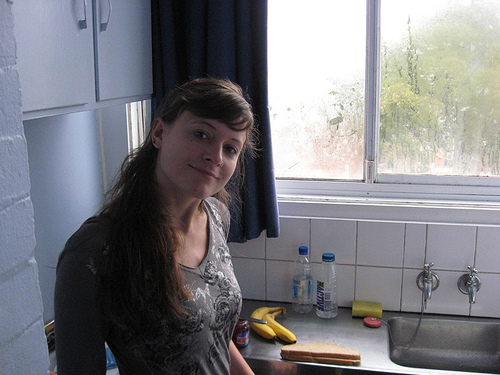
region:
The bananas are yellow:
[230, 295, 298, 347]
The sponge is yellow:
[350, 296, 386, 317]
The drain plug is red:
[362, 314, 387, 330]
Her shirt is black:
[109, 260, 245, 370]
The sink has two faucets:
[400, 250, 491, 317]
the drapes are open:
[230, 5, 493, 169]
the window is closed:
[208, 4, 495, 183]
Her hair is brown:
[181, 87, 237, 106]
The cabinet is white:
[0, 17, 159, 89]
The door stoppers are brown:
[267, 340, 363, 369]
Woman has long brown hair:
[105, 71, 251, 332]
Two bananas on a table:
[252, 296, 297, 344]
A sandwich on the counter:
[280, 333, 366, 365]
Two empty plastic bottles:
[292, 240, 344, 317]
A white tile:
[356, 220, 403, 266]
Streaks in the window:
[379, 12, 470, 157]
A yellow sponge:
[352, 297, 385, 315]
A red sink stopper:
[365, 315, 387, 328]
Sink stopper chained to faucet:
[363, 256, 438, 348]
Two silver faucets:
[413, 256, 483, 314]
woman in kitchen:
[47, 79, 254, 373]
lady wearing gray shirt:
[56, 78, 258, 374]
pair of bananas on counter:
[252, 305, 295, 348]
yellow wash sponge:
[351, 300, 383, 317]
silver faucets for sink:
[421, 260, 479, 307]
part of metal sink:
[387, 315, 498, 370]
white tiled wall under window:
[230, 218, 498, 317]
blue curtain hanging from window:
[150, 3, 278, 240]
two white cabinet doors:
[8, 0, 153, 120]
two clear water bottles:
[294, 248, 336, 322]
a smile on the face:
[173, 142, 261, 207]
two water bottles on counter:
[288, 241, 355, 321]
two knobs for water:
[405, 250, 497, 333]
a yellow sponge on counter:
[346, 292, 387, 324]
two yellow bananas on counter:
[248, 295, 311, 355]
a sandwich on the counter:
[271, 334, 389, 373]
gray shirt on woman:
[61, 193, 271, 370]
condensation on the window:
[285, 39, 486, 165]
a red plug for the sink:
[356, 312, 388, 328]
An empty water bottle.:
[280, 242, 318, 314]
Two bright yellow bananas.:
[251, 301, 298, 349]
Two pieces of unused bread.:
[275, 337, 367, 371]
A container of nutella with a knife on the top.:
[232, 314, 272, 352]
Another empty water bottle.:
[313, 248, 342, 328]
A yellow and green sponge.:
[350, 288, 387, 323]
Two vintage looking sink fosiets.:
[406, 258, 493, 319]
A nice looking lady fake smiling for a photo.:
[121, 65, 259, 205]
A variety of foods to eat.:
[236, 245, 356, 372]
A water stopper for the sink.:
[356, 314, 424, 354]